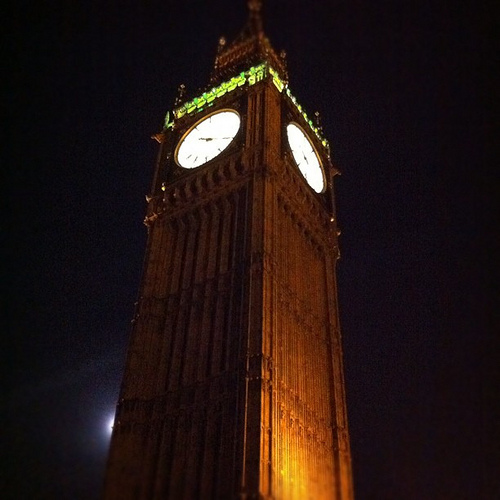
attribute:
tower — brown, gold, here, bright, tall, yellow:
[99, 0, 355, 499]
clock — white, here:
[172, 108, 240, 168]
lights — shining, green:
[174, 62, 266, 120]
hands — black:
[196, 133, 231, 142]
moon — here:
[104, 412, 116, 444]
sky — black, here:
[2, 2, 497, 499]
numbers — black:
[176, 112, 238, 163]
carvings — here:
[158, 151, 255, 209]